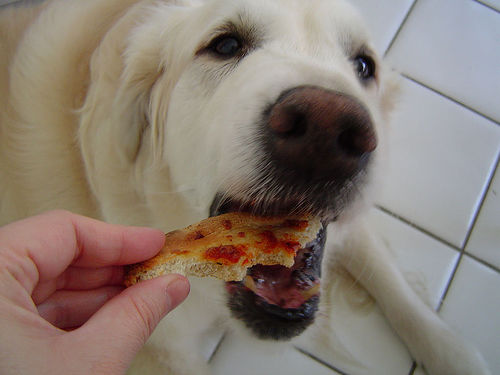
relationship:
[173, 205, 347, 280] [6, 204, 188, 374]
pizza crust in hand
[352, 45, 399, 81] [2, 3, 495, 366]
eye on dog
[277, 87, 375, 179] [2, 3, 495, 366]
nose on dog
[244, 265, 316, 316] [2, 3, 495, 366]
tongue on dog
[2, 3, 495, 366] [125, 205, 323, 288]
dog eating pizza crust